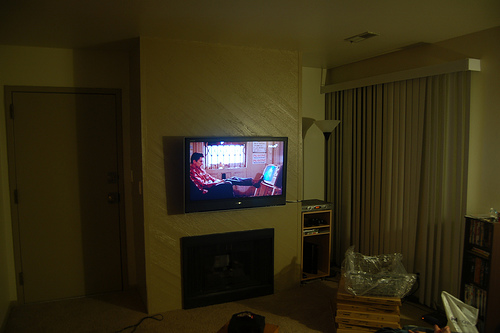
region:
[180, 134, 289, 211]
flatscreen tv is on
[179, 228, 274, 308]
fireplace under tv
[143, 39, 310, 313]
tan wall behind tv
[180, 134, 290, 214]
tv is hanging on the wall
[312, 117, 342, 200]
floor lamp is off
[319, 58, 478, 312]
tan colored vertical blinds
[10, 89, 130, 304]
door is closed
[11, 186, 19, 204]
hinges attached to door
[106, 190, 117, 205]
door knob attached to door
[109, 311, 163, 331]
black cable on floor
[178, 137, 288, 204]
screen on wall with image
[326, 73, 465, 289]
window in the room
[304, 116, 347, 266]
lamp by the wall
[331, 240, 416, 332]
boxes and packaging stacked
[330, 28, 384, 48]
vent on the ceiling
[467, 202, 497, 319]
shelf with items on it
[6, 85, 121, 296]
door to the room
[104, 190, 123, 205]
door knob on door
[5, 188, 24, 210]
middle hinge on door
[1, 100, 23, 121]
upper hinge on door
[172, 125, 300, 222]
A flat screen television is mounted to the wall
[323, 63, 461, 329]
White blinds are hanging on the side of the room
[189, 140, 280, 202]
The television is turned on to a program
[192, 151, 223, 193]
a man on the screen wears a red and white shirt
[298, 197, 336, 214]
A cable box can be seen on a shelf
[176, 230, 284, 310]
There is a black square below the television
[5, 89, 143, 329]
The door is closed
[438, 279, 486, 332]
A white plastic bag is in the foreground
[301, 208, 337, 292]
The entertainment center has two shelves in it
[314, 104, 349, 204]
standing lamp with white shade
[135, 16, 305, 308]
television screen over dark mantel on extended panel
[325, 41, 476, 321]
sheer draperies hanging from covered edging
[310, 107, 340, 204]
standing lamp with flared white shade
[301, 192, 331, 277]
wooden case with entertainment electronics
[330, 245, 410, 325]
plastic lining above cardboard box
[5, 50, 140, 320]
tan doorway in yellow wall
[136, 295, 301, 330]
small object on top of table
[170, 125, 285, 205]
screen showing man with foot pushing TV set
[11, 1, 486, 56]
flat ceiling with small panel near window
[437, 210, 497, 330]
folded paper in front of rack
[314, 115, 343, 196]
lamp in corner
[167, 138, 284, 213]
televeision on the wall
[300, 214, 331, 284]
shelf in the corner of room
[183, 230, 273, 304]
fireplace in the wall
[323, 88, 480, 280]
curtain cover window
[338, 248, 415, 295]
plastic on top of books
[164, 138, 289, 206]
flat screen tv on wall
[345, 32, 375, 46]
air vent on ceiling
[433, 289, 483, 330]
bag next to books